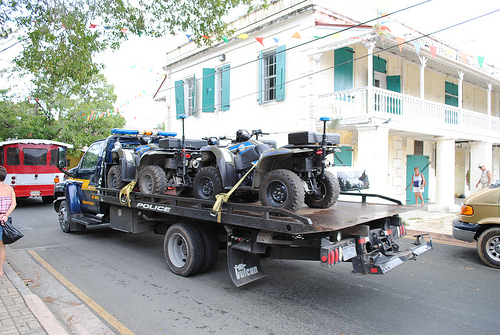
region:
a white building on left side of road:
[141, 4, 499, 204]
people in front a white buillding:
[388, 137, 499, 214]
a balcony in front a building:
[306, 30, 498, 147]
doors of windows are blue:
[171, 39, 289, 121]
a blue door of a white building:
[398, 143, 430, 210]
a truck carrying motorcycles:
[39, 116, 433, 286]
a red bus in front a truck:
[3, 123, 116, 223]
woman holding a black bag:
[1, 165, 22, 276]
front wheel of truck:
[48, 193, 80, 235]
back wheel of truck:
[151, 217, 215, 284]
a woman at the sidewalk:
[393, 146, 440, 208]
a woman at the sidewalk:
[391, 150, 463, 240]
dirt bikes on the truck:
[115, 103, 343, 235]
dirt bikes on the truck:
[70, 74, 412, 276]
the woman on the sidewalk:
[1, 163, 16, 275]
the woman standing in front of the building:
[409, 165, 427, 206]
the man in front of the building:
[475, 162, 491, 188]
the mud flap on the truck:
[227, 234, 267, 286]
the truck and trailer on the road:
[53, 128, 431, 288]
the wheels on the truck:
[162, 219, 220, 277]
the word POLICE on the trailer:
[135, 200, 170, 212]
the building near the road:
[153, 0, 498, 203]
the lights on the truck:
[112, 128, 178, 138]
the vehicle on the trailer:
[190, 117, 348, 213]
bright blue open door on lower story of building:
[406, 153, 429, 205]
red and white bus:
[1, 140, 69, 200]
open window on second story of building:
[265, 50, 276, 99]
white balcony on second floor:
[311, 83, 496, 132]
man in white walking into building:
[474, 164, 491, 189]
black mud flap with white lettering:
[226, 242, 266, 287]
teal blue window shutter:
[201, 67, 213, 113]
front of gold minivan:
[454, 183, 499, 265]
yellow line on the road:
[26, 247, 133, 334]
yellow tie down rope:
[212, 158, 258, 220]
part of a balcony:
[406, 132, 419, 141]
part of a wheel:
[290, 200, 295, 208]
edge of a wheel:
[203, 254, 208, 258]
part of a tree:
[80, 85, 87, 95]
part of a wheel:
[473, 235, 493, 257]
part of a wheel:
[176, 233, 191, 262]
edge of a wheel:
[274, 175, 281, 190]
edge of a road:
[38, 303, 65, 325]